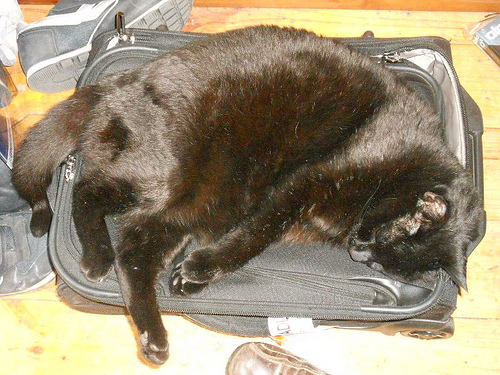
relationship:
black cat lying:
[67, 43, 465, 250] [114, 67, 491, 307]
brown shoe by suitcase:
[236, 348, 302, 373] [280, 268, 347, 307]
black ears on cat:
[67, 43, 465, 250] [335, 115, 498, 300]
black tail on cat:
[67, 43, 465, 250] [51, 113, 218, 249]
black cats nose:
[67, 43, 465, 250] [351, 235, 378, 264]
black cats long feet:
[67, 43, 465, 250] [108, 250, 250, 362]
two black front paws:
[108, 250, 250, 362] [85, 215, 268, 335]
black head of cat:
[67, 43, 465, 250] [335, 115, 498, 300]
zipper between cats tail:
[60, 158, 77, 190] [22, 75, 98, 246]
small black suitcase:
[114, 67, 491, 307] [280, 268, 347, 307]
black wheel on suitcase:
[271, 261, 342, 296] [392, 302, 458, 348]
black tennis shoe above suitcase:
[46, 37, 93, 56] [39, 11, 263, 62]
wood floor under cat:
[362, 13, 449, 34] [67, 43, 465, 250]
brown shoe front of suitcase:
[236, 348, 302, 373] [181, 298, 408, 375]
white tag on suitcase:
[275, 320, 324, 361] [280, 268, 347, 307]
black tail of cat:
[67, 43, 465, 250] [31, 95, 129, 229]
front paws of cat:
[152, 199, 306, 312] [31, 95, 129, 229]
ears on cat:
[403, 186, 495, 300] [335, 115, 498, 300]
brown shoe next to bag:
[236, 348, 302, 373] [290, 252, 377, 375]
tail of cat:
[22, 75, 98, 246] [114, 67, 491, 307]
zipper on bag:
[60, 158, 77, 190] [305, 254, 344, 294]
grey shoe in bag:
[424, 69, 462, 152] [426, 53, 475, 170]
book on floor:
[465, 12, 495, 56] [449, 11, 472, 64]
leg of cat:
[85, 191, 191, 353] [67, 43, 465, 250]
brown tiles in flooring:
[236, 348, 302, 373] [361, 3, 435, 33]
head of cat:
[366, 146, 479, 277] [67, 43, 465, 250]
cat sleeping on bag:
[67, 43, 465, 250] [305, 254, 344, 294]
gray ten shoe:
[38, 34, 70, 46] [28, 9, 201, 111]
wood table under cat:
[362, 13, 449, 34] [114, 67, 491, 307]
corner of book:
[469, 27, 490, 47] [465, 12, 495, 56]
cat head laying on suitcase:
[366, 146, 479, 277] [289, 259, 356, 314]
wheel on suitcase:
[363, 315, 458, 354] [280, 268, 347, 307]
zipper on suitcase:
[60, 158, 77, 190] [280, 268, 347, 307]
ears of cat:
[403, 186, 495, 300] [10, 24, 479, 365]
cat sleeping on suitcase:
[10, 24, 479, 365] [392, 302, 458, 348]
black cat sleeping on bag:
[67, 43, 465, 250] [305, 254, 344, 294]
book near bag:
[465, 12, 495, 56] [305, 254, 344, 294]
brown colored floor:
[236, 348, 302, 373] [449, 11, 472, 64]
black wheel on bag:
[271, 261, 342, 296] [392, 302, 458, 348]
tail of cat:
[22, 75, 98, 246] [10, 24, 479, 365]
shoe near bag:
[28, 9, 201, 111] [391, 48, 461, 100]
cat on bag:
[75, 24, 488, 352] [44, 13, 484, 338]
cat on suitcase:
[10, 24, 479, 365] [79, 17, 457, 347]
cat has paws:
[10, 24, 479, 365] [85, 215, 268, 335]